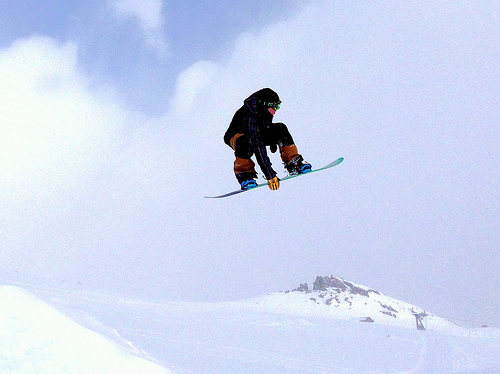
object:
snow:
[94, 291, 284, 371]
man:
[223, 86, 317, 190]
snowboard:
[203, 155, 350, 200]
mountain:
[278, 272, 465, 329]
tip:
[308, 275, 357, 293]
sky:
[1, 2, 497, 249]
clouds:
[101, 0, 181, 63]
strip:
[250, 114, 272, 188]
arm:
[253, 118, 266, 176]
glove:
[268, 178, 281, 190]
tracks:
[1, 293, 498, 372]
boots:
[241, 162, 317, 191]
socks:
[231, 173, 260, 178]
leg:
[233, 140, 256, 186]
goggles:
[272, 106, 281, 112]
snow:
[252, 289, 461, 332]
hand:
[264, 172, 284, 191]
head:
[254, 89, 278, 116]